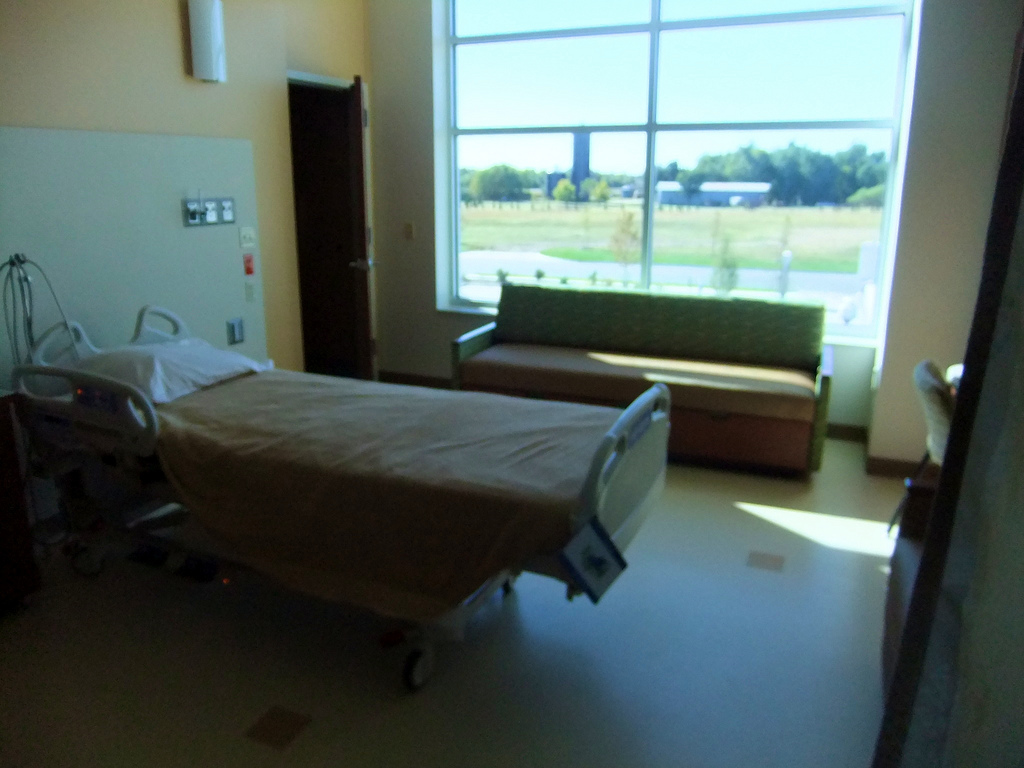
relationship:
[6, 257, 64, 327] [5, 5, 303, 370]
gadget on wall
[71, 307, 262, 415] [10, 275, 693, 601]
pillow on bed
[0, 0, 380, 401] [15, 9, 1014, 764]
wall in building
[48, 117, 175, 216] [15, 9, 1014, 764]
wall side building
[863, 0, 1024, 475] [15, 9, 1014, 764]
outside wall side building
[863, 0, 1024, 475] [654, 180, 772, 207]
outside wall in barn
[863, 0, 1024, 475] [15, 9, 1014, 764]
outside wall in building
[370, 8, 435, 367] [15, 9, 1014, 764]
outside wall side building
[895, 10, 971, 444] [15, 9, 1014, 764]
outside wall side building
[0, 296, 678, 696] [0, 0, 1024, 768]
bed in building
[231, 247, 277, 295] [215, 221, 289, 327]
switch on wall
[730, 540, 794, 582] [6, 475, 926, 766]
tile on floor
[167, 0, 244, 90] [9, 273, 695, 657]
light above bed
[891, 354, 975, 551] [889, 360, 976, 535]
chair pushed up to chair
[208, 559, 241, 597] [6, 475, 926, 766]
dot on floor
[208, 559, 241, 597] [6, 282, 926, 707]
dot under bed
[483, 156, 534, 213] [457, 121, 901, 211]
tree in woods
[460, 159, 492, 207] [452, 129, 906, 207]
tree in woods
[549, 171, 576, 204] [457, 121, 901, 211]
tree in woods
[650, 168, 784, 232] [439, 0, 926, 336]
barn outside window